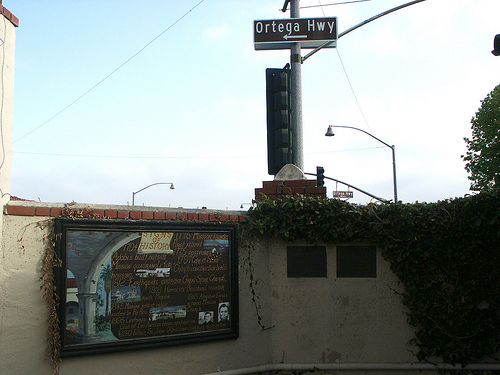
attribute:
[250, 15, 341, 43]
directional sign — pictured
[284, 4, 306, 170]
utility pole — made of steel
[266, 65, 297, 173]
traffic light — black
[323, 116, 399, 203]
streetlight — hanging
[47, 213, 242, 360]
picture — old, large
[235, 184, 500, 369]
ivy — green, not living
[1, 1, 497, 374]
wall — beige, cream colored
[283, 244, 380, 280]
plaques — small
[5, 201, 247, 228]
edge of building — made of bricks, in a line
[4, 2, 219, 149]
electrical wire — running, strung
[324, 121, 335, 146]
street light — hanging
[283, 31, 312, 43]
arrow — white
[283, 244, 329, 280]
square — black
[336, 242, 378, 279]
square — black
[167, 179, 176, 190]
streetlight — hanging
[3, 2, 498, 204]
sky — blue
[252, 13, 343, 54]
sign — road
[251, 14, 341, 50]
sign — road